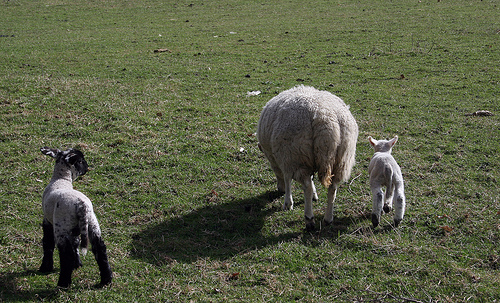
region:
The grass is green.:
[106, 83, 203, 178]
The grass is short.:
[103, 100, 190, 187]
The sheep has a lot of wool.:
[235, 77, 360, 199]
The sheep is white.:
[242, 79, 362, 225]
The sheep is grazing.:
[246, 82, 360, 222]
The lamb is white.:
[360, 125, 414, 227]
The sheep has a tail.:
[299, 103, 351, 199]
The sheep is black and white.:
[13, 128, 133, 296]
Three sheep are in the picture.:
[18, 55, 443, 300]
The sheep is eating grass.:
[237, 72, 362, 235]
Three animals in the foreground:
[23, 76, 430, 295]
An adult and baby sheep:
[242, 70, 427, 247]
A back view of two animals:
[243, 71, 437, 254]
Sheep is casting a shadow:
[120, 176, 303, 270]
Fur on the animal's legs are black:
[22, 214, 133, 299]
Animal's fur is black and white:
[9, 128, 139, 290]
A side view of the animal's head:
[44, 141, 101, 188]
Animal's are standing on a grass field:
[1, 5, 496, 299]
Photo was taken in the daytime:
[8, 6, 497, 298]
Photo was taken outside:
[8, 3, 490, 295]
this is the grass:
[132, 44, 239, 113]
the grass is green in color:
[81, 39, 122, 64]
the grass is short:
[55, 35, 105, 65]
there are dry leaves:
[148, 39, 295, 67]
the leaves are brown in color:
[151, 33, 315, 73]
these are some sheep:
[37, 77, 415, 284]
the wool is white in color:
[48, 190, 67, 208]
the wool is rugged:
[268, 104, 324, 155]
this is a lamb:
[361, 134, 414, 213]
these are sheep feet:
[280, 177, 355, 228]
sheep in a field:
[26, 50, 487, 270]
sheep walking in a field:
[39, 18, 492, 280]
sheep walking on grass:
[22, 85, 436, 302]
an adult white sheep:
[235, 70, 357, 233]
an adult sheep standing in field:
[227, 42, 364, 256]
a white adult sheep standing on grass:
[239, 68, 367, 219]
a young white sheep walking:
[369, 117, 454, 239]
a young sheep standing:
[17, 114, 143, 292]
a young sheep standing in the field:
[18, 118, 148, 302]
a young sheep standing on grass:
[7, 121, 132, 286]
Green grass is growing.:
[37, 16, 282, 69]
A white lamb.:
[362, 130, 417, 235]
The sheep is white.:
[246, 65, 352, 230]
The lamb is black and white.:
[30, 140, 115, 290]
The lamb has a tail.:
[70, 197, 90, 252]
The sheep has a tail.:
[315, 110, 342, 190]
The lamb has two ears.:
[361, 125, 411, 150]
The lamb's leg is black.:
[55, 230, 77, 295]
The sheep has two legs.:
[295, 170, 347, 235]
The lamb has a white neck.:
[43, 164, 86, 189]